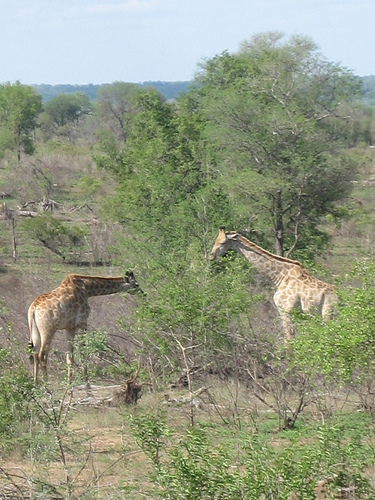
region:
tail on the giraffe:
[26, 312, 33, 355]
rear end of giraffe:
[21, 303, 44, 321]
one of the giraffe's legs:
[68, 332, 76, 400]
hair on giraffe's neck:
[81, 271, 120, 281]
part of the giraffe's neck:
[89, 277, 123, 293]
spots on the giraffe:
[63, 296, 84, 316]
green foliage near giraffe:
[306, 324, 360, 364]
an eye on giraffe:
[219, 240, 227, 246]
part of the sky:
[54, 20, 186, 49]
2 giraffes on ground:
[15, 228, 340, 407]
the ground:
[102, 415, 286, 485]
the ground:
[137, 375, 318, 493]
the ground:
[172, 409, 270, 499]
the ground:
[157, 417, 228, 490]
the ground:
[121, 362, 191, 487]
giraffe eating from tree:
[27, 268, 148, 386]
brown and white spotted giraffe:
[25, 268, 149, 389]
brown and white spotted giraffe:
[208, 224, 341, 369]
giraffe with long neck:
[76, 271, 125, 296]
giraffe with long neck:
[237, 234, 288, 287]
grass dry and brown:
[0, 156, 372, 496]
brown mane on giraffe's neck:
[231, 230, 302, 269]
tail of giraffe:
[27, 309, 33, 349]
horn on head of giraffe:
[220, 223, 225, 235]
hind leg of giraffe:
[37, 330, 49, 394]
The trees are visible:
[155, 402, 227, 492]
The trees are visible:
[196, 448, 261, 495]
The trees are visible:
[157, 371, 211, 438]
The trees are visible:
[174, 456, 185, 462]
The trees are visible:
[169, 381, 250, 482]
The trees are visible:
[192, 428, 287, 494]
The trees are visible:
[115, 112, 182, 273]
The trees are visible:
[124, 125, 214, 181]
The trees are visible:
[54, 167, 317, 234]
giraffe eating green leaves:
[201, 220, 356, 377]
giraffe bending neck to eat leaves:
[13, 246, 154, 399]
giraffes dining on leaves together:
[16, 208, 357, 419]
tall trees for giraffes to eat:
[68, 114, 303, 201]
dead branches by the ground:
[127, 349, 274, 435]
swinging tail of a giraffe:
[16, 312, 42, 366]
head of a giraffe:
[204, 220, 243, 272]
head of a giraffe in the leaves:
[120, 264, 153, 310]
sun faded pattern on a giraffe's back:
[257, 260, 329, 318]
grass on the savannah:
[84, 402, 133, 482]